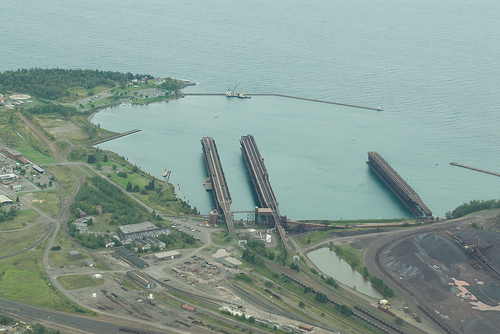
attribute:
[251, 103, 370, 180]
water — body, small, large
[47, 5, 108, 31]
clouds — white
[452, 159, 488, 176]
pier — alone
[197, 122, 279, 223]
piers — paired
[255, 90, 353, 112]
wall — barrier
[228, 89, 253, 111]
boat — small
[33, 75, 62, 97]
trees — clustered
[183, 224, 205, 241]
cars — parked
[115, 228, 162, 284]
buildings — clustered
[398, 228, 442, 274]
pile — huge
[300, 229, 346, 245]
grass — patched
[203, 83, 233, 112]
area — closed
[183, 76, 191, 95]
docking — extended